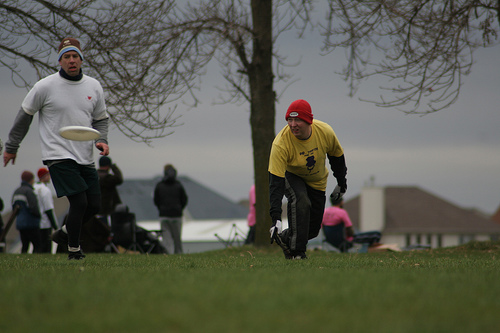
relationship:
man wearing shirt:
[6, 71, 110, 259] [22, 72, 109, 166]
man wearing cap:
[270, 98, 347, 258] [285, 100, 312, 125]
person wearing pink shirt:
[320, 196, 381, 251] [321, 206, 353, 242]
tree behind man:
[0, 1, 500, 246] [270, 98, 347, 258]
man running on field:
[6, 71, 110, 259] [0, 241, 500, 332]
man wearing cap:
[6, 71, 110, 259] [285, 100, 312, 125]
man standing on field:
[6, 71, 110, 259] [0, 241, 500, 332]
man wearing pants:
[270, 98, 347, 258] [279, 172, 326, 251]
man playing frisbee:
[6, 71, 110, 259] [58, 126, 102, 142]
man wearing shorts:
[6, 71, 110, 259] [44, 162, 102, 198]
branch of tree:
[337, 1, 368, 97] [0, 1, 500, 246]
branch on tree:
[337, 1, 368, 97] [0, 1, 500, 246]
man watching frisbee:
[270, 98, 347, 258] [58, 126, 102, 142]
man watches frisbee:
[6, 71, 110, 259] [58, 126, 102, 142]